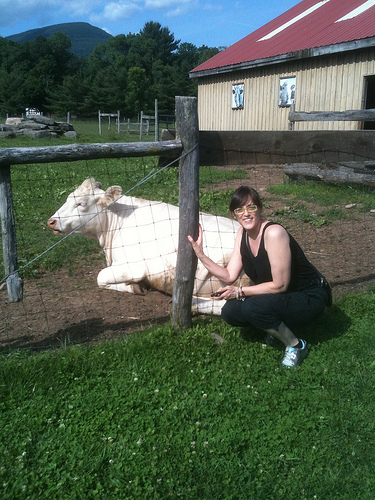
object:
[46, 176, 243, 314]
cow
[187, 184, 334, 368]
woman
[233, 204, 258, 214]
glasses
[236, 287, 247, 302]
bracelets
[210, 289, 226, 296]
cellphone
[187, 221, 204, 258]
hand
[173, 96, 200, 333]
post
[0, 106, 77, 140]
rocks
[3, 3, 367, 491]
farm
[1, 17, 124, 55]
mountain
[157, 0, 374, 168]
barn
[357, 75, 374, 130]
door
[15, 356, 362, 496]
grass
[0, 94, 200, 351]
fence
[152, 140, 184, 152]
wood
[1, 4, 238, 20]
sky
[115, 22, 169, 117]
trees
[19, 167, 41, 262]
grass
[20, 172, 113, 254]
wire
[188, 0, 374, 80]
roof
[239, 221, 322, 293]
tank top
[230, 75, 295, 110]
two windows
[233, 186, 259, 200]
dark hair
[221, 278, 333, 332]
pants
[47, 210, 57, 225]
nose